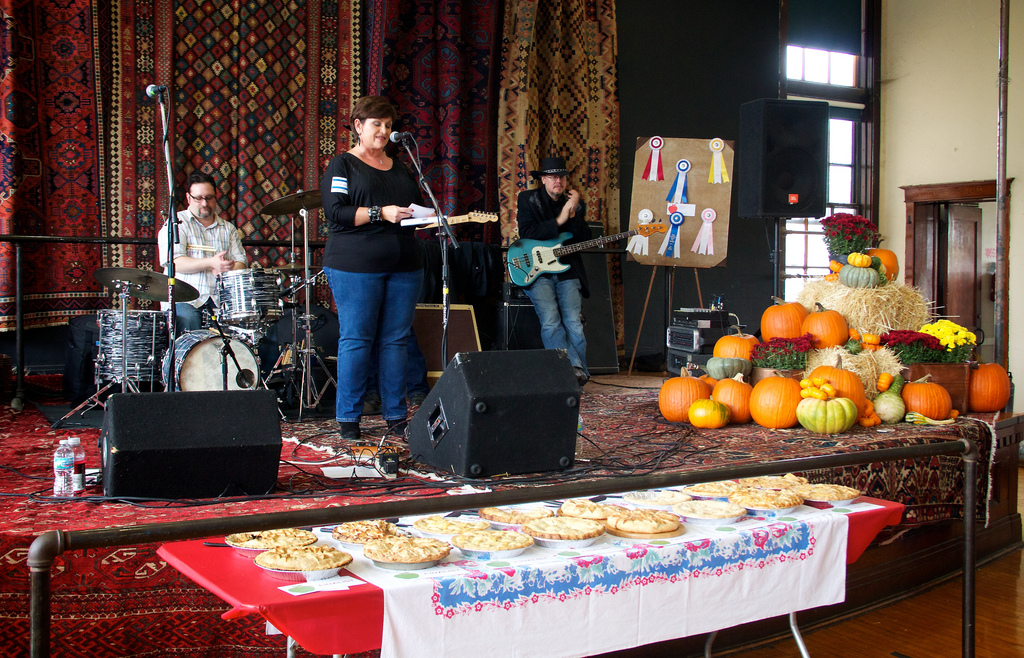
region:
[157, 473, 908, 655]
pies on top of table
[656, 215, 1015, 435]
pumpkins on top of stage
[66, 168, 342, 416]
man playing the drums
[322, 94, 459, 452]
woman speaking on a microphone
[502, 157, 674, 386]
man holding a guitar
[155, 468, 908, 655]
the table is red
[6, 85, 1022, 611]
people on top of a stage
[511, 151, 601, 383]
man wearing black hat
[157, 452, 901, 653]
table has a tablecloth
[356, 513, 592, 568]
the pies are on the table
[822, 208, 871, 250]
the flowers are red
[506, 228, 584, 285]
the guitar is teal in color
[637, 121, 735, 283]
the ribbons are on the display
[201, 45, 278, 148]
the curtain is colorful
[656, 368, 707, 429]
orange pumpkin on the stage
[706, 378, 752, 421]
orange pumpkin on the stage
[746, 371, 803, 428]
orange pumpkin on the stage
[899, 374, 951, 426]
orange pumpkin on the stage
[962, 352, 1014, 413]
orange pumpkin on the stage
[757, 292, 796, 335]
orange pumpkin on the stage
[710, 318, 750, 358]
orange pumpkin on the stage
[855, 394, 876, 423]
orange pumpkin on the stage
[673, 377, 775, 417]
Several pumpkins laid on a platform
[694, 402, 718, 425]
A small yellow pumpkin laid on the surface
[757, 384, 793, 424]
A big yellow pumpkin between others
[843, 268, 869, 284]
A green pumpkin sitting on a straw base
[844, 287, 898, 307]
A base of straw supporting pumpkins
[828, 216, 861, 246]
A bouquet of red flowers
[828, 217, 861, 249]
A bouquet of flowers next to pumpkins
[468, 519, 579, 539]
Pumpkin pies set on a table